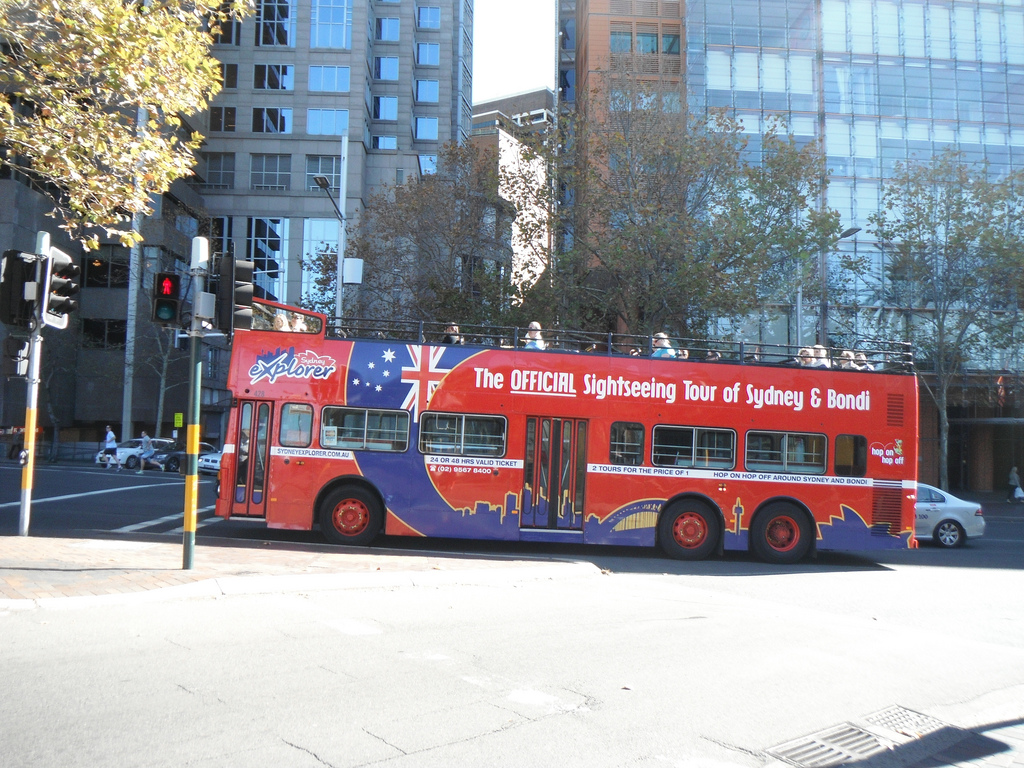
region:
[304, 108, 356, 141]
window is clean and clear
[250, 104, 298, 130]
window is clean and clear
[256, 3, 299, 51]
window is clean and clear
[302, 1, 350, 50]
window is clean and clear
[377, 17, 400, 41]
window is clean and clear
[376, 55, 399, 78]
window is clean and clear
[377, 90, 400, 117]
window is clean and clear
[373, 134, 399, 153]
window is clean and clear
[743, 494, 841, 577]
tire on a bus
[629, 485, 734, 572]
tire on a bus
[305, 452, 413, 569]
tire on a bus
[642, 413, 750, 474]
window on a bus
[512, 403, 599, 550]
door on a bus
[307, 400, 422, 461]
window on a bus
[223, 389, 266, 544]
door on a bus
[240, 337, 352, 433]
sign on a bus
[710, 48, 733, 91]
window facing red passenger bus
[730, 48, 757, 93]
window facing red passenger bus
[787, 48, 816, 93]
window facing red passenger bus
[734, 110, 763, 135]
window facing red passenger bus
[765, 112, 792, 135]
window facing red passenger bus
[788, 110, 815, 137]
window facing red passenger bus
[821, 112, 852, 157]
window facing red passenger bus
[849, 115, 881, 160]
window facing red passenger bus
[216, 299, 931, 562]
red and blue bus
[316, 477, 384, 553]
black tire with red hubcap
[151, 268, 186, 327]
do not walk signal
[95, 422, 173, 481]
people crossing the street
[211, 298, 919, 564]
bus with people sitting on top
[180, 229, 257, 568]
traffic light on a pole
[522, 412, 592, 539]
red trimmed doors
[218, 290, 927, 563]
people sitting on top of a bus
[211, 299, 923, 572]
red, white, and blue tour bus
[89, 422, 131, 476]
man walking dog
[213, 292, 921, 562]
double decker bus has people on top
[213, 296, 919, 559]
bus is red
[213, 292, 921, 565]
bus is a double decker bus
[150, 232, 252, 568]
traffic light is on sidewalk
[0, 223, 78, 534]
traffic light is on sidewalk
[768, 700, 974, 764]
water drain on sidewalk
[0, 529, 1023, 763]
sidewalk beside street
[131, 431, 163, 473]
person running across the street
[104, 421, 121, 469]
person running across the street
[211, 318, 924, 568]
red and blue public bus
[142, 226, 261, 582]
metal post with traffic lights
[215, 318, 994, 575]
grey car behind bus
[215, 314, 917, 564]
bus with three visible wheels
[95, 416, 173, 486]
people walking across street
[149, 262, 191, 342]
red lit crosswalk light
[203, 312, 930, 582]
white writing on side of bus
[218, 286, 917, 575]
people on top of bus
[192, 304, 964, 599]
A red long double decked bus.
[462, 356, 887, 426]
White writing on the bus.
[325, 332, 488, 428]
A British flag painted on the bus.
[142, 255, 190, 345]
A red don't walk light.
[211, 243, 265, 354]
A traffic light facing away.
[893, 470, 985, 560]
The back end of a car behind the bus.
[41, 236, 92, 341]
A traffic light on red.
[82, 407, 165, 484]
Two people running across the street.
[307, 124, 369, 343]
A light pole behind the bus.